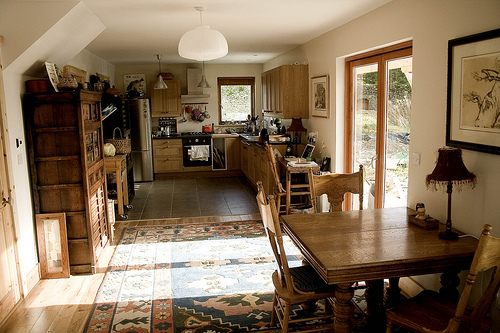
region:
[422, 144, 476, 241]
Decorative lamp on table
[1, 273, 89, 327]
Hardwood floor of room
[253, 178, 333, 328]
Wooden dining table chair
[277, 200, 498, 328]
Wooden dining table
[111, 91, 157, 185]
Stainless steel refrigerator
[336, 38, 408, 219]
Sliding glass door in room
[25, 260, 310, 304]
Sunshine on floor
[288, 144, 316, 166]
Laptop computer on stool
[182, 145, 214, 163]
Dish towels draped on oven door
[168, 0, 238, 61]
White round ceiling light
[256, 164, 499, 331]
a wooden table with three wooden chairs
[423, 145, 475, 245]
a red lamp on a table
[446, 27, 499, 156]
a framed drawing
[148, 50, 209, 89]
silver light fixtures on the ceiling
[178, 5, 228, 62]
a white lamp hanging from the ceiling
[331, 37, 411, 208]
a wooden patio door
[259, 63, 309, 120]
wooden cabinets in a kitchen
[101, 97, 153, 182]
a silver refrigerator in a kitchen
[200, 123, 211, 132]
an orange pot on a stove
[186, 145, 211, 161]
dish washing cloth on an oven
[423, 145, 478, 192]
Dark beaded lamp shade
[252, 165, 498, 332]
Three wood chairs around a table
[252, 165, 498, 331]
Wood table and chair set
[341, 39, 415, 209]
Two glass doors with wood frame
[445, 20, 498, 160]
Painting with white matting and black frame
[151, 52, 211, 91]
Two hanging metal light fixtures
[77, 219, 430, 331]
Large patterned floor rug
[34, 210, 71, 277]
Mirror with thick wood frame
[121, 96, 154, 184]
Two door metal refrigerator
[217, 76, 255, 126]
Kitchen window with wood framing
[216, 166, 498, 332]
Three brown chairs are tucked into the table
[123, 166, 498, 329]
Table is sitting on top of a large carpet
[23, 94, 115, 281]
A framed picture is leaning against a cabinet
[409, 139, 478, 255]
This lamp is on top of the table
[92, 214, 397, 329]
Large carpet is blue, red and white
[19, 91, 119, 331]
Cabinet is on light brown wood floor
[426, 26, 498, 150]
Painting hanged against the wall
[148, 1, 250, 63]
White semi-circle light on the ceiling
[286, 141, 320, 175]
White computer on the top of a small desk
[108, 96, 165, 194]
Metal refrigerator with a handle on the right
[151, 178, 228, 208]
tile floor in the kitchen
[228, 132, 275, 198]
wood cabinets in the kitchen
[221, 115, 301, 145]
black counter tops in the kitchen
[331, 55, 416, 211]
sliding glass door with a view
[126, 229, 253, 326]
an aztec style rug on the floor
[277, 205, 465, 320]
an old woodem table in the room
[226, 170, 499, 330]
a dining table with chairs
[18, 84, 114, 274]
an old wood chest for storage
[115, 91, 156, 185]
stainless steel refridgerator in the kitchen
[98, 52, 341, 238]
open floor plan in the kitchen